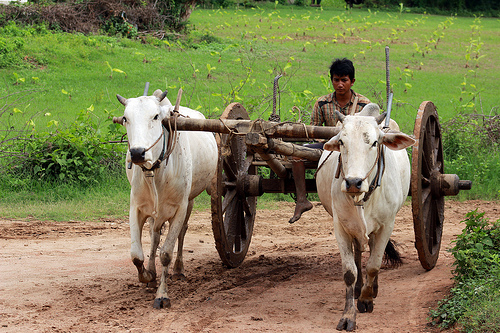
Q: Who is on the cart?
A: A man.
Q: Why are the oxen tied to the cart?
A: To pull it.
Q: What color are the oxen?
A: White.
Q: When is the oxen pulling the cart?
A: Daytime.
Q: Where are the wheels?
A: On both sides of the cart.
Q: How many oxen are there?
A: Two.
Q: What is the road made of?
A: Dirt.